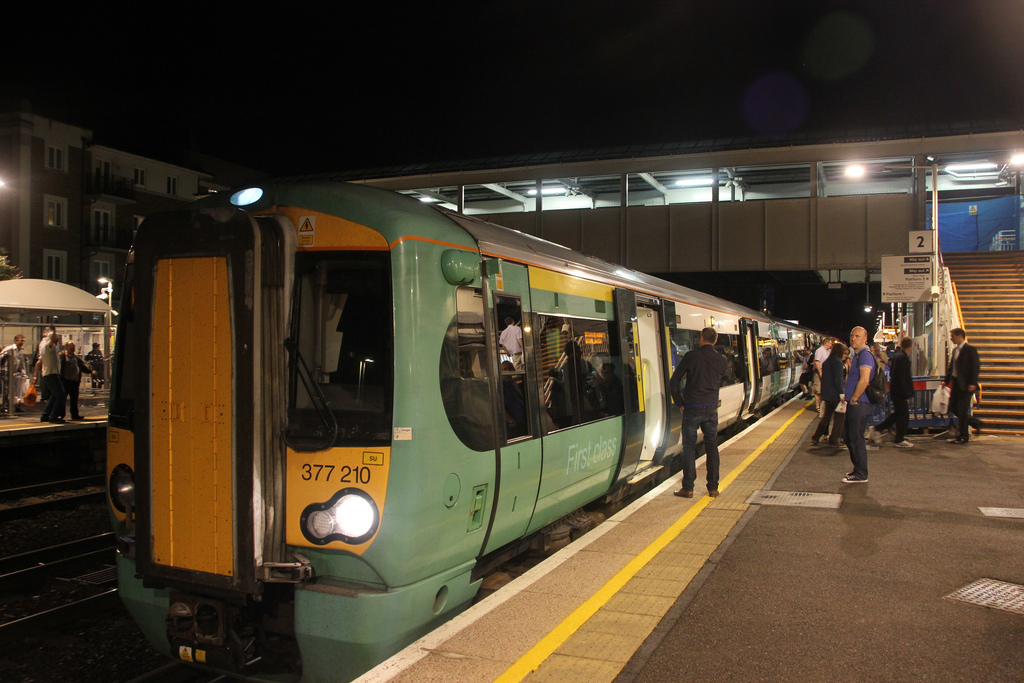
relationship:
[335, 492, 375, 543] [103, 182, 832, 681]
headlight on top of train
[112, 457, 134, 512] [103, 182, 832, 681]
headlight on top of train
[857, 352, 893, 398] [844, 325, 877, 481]
backpack hanging on man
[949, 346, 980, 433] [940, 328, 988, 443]
suit on top of man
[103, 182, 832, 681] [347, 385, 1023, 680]
train next to platform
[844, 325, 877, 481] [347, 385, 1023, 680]
man on top of platform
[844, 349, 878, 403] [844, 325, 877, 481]
shirt on top of man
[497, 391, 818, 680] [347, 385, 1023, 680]
line on top of platform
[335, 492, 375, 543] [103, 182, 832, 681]
headlight on front of train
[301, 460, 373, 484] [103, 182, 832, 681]
numbers are on front of train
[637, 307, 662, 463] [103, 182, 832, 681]
doorway on side of train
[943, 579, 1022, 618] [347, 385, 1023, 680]
square on top of platform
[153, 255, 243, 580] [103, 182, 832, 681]
door on front of train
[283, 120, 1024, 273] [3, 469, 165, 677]
walkway above track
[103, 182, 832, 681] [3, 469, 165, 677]
train on top of track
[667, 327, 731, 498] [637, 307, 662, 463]
man next to doorway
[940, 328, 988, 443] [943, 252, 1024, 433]
man next to stairway